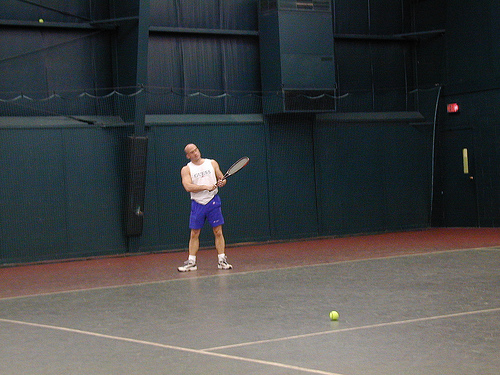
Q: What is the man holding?
A: A tennis racket.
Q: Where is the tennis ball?
A: On the ground.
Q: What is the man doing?
A: Playing tennis.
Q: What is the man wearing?
A: Tank top and shorts.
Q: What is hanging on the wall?
A: Ventilation system.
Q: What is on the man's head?
A: Nothing.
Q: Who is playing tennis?
A: Man in blue shorts.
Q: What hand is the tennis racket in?
A: Both hands.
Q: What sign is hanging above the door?
A: Exit.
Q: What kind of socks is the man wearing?
A: White ankle socks.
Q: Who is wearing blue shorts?
A: Man playing tennis.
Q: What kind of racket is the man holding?
A: Tennis.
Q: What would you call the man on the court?
A: Athlete.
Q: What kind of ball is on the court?
A: Tennis?.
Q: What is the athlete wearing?
A: White shirt.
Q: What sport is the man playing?
A: Tennis.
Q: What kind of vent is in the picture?
A: Air conditioner.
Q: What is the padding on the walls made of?
A: Foam.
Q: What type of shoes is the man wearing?
A: Tennis.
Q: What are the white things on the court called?
A: Lines.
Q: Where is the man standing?
A: Tennis court.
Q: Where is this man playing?
A: Tennis court.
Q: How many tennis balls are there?
A: One.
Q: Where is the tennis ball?
A: Ground.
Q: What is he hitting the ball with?
A: Racket.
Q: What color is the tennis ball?
A: Yellow.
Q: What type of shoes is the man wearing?
A: Sneakers.